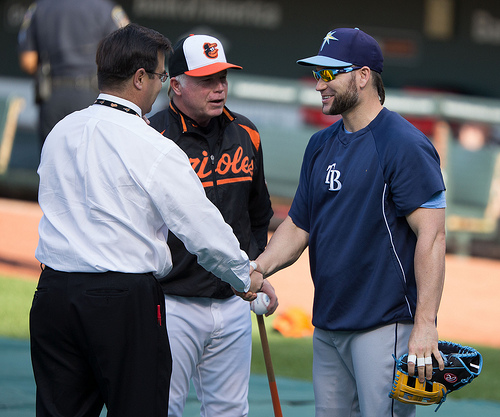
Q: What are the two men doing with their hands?
A: Shaking hands.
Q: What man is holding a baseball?
A: White shirt.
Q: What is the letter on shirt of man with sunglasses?
A: B.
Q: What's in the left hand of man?
A: Catchers glove.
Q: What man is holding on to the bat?
A: Middle.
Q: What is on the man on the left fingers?
A: Bandaids.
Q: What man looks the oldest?
A: Middle man.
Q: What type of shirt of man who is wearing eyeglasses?
A: Dress.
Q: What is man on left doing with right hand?
A: Shaking hands.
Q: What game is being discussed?
A: Baseball.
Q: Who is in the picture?
A: Three men.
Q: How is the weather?
A: Clear.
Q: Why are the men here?
A: They are talking.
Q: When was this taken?
A: During the day.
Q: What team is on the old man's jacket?
A: The Orioles.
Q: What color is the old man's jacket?
A: Black and orange.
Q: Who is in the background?
A: A police officer.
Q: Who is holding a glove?
A: The baseball player.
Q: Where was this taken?
A: At a baseball field.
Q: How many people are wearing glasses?
A: Two.